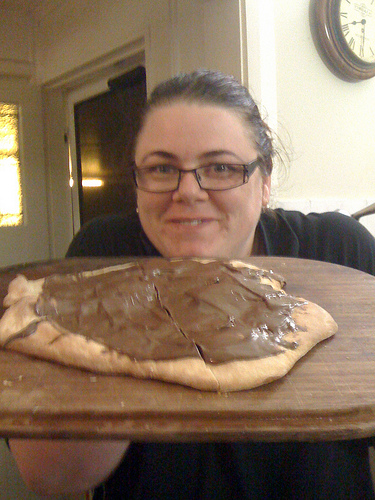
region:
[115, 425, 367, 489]
womans shirt is black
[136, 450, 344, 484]
womans shirt is black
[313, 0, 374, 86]
clock on the wall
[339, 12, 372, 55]
hands on a clock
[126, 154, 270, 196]
brown framed classes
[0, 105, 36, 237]
light shining through a window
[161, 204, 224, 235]
a big toothy smile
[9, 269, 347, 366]
chocolate on a crust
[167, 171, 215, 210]
a nose on a face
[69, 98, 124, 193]
light coming through a window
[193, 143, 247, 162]
eyebrows on a face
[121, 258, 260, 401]
cut in a dessert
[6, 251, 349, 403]
bread with chocolate on top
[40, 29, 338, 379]
a woman experimenting with cooking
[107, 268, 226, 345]
a dark chocolate spread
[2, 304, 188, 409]
a pizza like crust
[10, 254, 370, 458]
a wooden serving platter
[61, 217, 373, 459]
a dark colored shirt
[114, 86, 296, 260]
a dark haired woman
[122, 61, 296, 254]
a woman wearing glasses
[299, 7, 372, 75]
a wood framed clock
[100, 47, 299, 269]
a young, smiling woman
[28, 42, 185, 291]
a white door frame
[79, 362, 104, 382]
crumb on wooden plate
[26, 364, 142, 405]
crumb on wooden plate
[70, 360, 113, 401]
crumb on wooden plate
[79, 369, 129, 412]
crumb on wooden plate